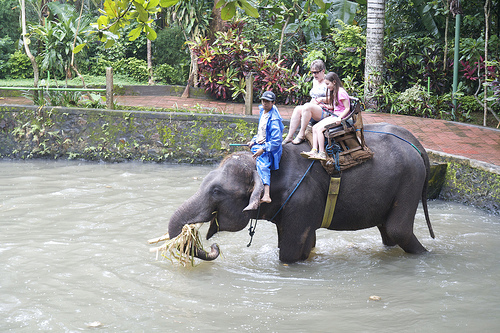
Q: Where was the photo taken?
A: It was taken at the forest.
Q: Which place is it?
A: It is a forest.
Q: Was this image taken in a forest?
A: Yes, it was taken in a forest.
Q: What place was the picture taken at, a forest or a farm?
A: It was taken at a forest.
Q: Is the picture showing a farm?
A: No, the picture is showing a forest.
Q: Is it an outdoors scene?
A: Yes, it is outdoors.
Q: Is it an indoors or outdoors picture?
A: It is outdoors.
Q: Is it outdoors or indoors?
A: It is outdoors.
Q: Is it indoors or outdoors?
A: It is outdoors.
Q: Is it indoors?
A: No, it is outdoors.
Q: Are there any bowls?
A: No, there are no bowls.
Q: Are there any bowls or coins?
A: No, there are no bowls or coins.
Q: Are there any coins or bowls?
A: No, there are no bowls or coins.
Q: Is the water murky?
A: Yes, the water is murky.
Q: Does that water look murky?
A: Yes, the water is murky.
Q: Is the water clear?
A: No, the water is murky.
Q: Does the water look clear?
A: No, the water is murky.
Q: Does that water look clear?
A: No, the water is murky.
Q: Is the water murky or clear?
A: The water is murky.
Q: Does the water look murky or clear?
A: The water is murky.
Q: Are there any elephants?
A: Yes, there is an elephant.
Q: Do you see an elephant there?
A: Yes, there is an elephant.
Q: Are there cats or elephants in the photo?
A: Yes, there is an elephant.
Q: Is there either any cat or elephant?
A: Yes, there is an elephant.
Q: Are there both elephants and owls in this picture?
A: No, there is an elephant but no owls.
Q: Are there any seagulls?
A: No, there are no seagulls.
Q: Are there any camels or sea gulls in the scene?
A: No, there are no sea gulls or camels.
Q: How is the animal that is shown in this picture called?
A: The animal is an elephant.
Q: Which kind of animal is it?
A: The animal is an elephant.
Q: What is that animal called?
A: This is an elephant.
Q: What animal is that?
A: This is an elephant.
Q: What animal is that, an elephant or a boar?
A: This is an elephant.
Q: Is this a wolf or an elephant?
A: This is an elephant.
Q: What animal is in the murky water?
A: The elephant is in the water.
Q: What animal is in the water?
A: The elephant is in the water.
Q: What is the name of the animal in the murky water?
A: The animal is an elephant.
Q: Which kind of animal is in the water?
A: The animal is an elephant.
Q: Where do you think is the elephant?
A: The elephant is in the water.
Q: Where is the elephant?
A: The elephant is in the water.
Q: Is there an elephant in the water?
A: Yes, there is an elephant in the water.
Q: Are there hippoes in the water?
A: No, there is an elephant in the water.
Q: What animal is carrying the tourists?
A: The elephant is carrying the tourists.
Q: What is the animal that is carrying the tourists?
A: The animal is an elephant.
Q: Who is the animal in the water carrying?
A: The elephant is carrying tourists.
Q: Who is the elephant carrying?
A: The elephant is carrying tourists.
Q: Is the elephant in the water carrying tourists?
A: Yes, the elephant is carrying tourists.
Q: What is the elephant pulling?
A: The elephant is pulling the leaves.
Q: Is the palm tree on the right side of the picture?
A: Yes, the palm tree is on the right of the image.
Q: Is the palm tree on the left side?
A: No, the palm tree is on the right of the image.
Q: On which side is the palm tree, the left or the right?
A: The palm tree is on the right of the image.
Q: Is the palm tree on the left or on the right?
A: The palm tree is on the right of the image.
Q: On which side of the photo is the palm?
A: The palm is on the right of the image.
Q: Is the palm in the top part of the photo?
A: Yes, the palm is in the top of the image.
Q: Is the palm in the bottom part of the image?
A: No, the palm is in the top of the image.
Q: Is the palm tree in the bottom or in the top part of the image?
A: The palm tree is in the top of the image.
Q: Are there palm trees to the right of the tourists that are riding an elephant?
A: Yes, there is a palm tree to the right of the tourists.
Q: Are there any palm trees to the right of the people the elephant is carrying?
A: Yes, there is a palm tree to the right of the tourists.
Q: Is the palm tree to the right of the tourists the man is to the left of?
A: Yes, the palm tree is to the right of the tourists.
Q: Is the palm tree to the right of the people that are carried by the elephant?
A: Yes, the palm tree is to the right of the tourists.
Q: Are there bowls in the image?
A: No, there are no bowls.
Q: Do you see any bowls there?
A: No, there are no bowls.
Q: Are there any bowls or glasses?
A: No, there are no bowls or glasses.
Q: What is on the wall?
A: The moss is on the wall.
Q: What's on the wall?
A: The moss is on the wall.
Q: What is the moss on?
A: The moss is on the wall.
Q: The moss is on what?
A: The moss is on the wall.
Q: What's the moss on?
A: The moss is on the wall.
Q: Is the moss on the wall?
A: Yes, the moss is on the wall.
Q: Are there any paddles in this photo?
A: No, there are no paddles.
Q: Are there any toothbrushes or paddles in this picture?
A: No, there are no paddles or toothbrushes.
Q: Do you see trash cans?
A: No, there are no trash cans.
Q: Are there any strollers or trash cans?
A: No, there are no trash cans or strollers.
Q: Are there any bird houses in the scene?
A: No, there are no bird houses.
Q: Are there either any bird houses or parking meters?
A: No, there are no bird houses or parking meters.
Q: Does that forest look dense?
A: Yes, the forest is dense.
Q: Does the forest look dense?
A: Yes, the forest is dense.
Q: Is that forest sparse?
A: No, the forest is dense.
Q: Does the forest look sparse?
A: No, the forest is dense.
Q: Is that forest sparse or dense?
A: The forest is dense.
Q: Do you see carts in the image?
A: No, there are no carts.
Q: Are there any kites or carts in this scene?
A: No, there are no carts or kites.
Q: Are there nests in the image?
A: No, there are no nests.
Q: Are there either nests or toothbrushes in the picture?
A: No, there are no nests or toothbrushes.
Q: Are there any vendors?
A: No, there are no vendors.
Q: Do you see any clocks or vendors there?
A: No, there are no vendors or clocks.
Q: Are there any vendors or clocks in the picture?
A: No, there are no vendors or clocks.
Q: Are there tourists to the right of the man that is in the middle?
A: Yes, there are tourists to the right of the man.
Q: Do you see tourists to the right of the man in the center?
A: Yes, there are tourists to the right of the man.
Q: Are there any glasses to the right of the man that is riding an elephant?
A: No, there are tourists to the right of the man.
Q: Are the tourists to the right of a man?
A: Yes, the tourists are to the right of a man.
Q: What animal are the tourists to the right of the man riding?
A: The tourists are riding an elephant.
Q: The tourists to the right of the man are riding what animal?
A: The tourists are riding an elephant.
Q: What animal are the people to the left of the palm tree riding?
A: The tourists are riding an elephant.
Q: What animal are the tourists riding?
A: The tourists are riding an elephant.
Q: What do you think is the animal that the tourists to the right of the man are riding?
A: The animal is an elephant.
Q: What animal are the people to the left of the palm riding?
A: The tourists are riding an elephant.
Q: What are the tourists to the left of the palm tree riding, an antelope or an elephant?
A: The tourists are riding an elephant.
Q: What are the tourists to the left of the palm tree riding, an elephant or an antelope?
A: The tourists are riding an elephant.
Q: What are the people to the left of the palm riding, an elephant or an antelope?
A: The tourists are riding an elephant.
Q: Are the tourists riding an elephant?
A: Yes, the tourists are riding an elephant.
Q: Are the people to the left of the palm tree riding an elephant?
A: Yes, the tourists are riding an elephant.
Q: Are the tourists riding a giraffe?
A: No, the tourists are riding an elephant.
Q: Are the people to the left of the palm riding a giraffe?
A: No, the tourists are riding an elephant.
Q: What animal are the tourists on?
A: The tourists are on the elephant.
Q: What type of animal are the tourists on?
A: The tourists are on the elephant.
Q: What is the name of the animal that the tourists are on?
A: The animal is an elephant.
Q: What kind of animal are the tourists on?
A: The tourists are on the elephant.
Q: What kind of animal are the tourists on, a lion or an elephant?
A: The tourists are on an elephant.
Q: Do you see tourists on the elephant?
A: Yes, there are tourists on the elephant.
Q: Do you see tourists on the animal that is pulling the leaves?
A: Yes, there are tourists on the elephant.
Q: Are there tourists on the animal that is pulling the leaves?
A: Yes, there are tourists on the elephant.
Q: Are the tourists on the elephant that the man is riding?
A: Yes, the tourists are on the elephant.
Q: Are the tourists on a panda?
A: No, the tourists are on the elephant.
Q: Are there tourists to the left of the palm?
A: Yes, there are tourists to the left of the palm.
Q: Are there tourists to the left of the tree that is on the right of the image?
A: Yes, there are tourists to the left of the palm.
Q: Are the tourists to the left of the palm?
A: Yes, the tourists are to the left of the palm.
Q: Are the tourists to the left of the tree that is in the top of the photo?
A: Yes, the tourists are to the left of the palm.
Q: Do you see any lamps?
A: No, there are no lamps.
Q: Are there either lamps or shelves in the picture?
A: No, there are no lamps or shelves.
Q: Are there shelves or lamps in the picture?
A: No, there are no lamps or shelves.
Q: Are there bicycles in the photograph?
A: No, there are no bicycles.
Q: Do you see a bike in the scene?
A: No, there are no bikes.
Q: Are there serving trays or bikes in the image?
A: No, there are no bikes or serving trays.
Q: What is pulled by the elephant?
A: The leaves are pulled by the elephant.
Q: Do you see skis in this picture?
A: No, there are no skis.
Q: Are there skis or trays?
A: No, there are no skis or trays.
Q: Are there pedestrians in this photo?
A: No, there are no pedestrians.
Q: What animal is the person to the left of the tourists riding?
A: The man is riding an elephant.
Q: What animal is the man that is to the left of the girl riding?
A: The man is riding an elephant.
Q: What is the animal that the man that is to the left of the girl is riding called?
A: The animal is an elephant.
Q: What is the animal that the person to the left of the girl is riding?
A: The animal is an elephant.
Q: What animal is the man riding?
A: The man is riding an elephant.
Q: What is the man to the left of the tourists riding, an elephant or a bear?
A: The man is riding an elephant.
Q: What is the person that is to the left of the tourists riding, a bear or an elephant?
A: The man is riding an elephant.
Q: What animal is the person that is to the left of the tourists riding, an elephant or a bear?
A: The man is riding an elephant.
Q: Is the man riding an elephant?
A: Yes, the man is riding an elephant.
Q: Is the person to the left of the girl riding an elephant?
A: Yes, the man is riding an elephant.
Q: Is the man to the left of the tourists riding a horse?
A: No, the man is riding an elephant.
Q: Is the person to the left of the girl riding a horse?
A: No, the man is riding an elephant.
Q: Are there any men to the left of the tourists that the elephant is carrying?
A: Yes, there is a man to the left of the tourists.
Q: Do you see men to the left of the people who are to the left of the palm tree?
A: Yes, there is a man to the left of the tourists.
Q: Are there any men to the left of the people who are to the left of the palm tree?
A: Yes, there is a man to the left of the tourists.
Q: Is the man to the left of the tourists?
A: Yes, the man is to the left of the tourists.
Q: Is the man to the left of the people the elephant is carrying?
A: Yes, the man is to the left of the tourists.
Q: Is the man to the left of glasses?
A: No, the man is to the left of the tourists.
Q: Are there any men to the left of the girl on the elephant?
A: Yes, there is a man to the left of the girl.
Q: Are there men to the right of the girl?
A: No, the man is to the left of the girl.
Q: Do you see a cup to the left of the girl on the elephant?
A: No, there is a man to the left of the girl.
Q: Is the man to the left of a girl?
A: Yes, the man is to the left of a girl.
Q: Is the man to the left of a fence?
A: No, the man is to the left of a girl.